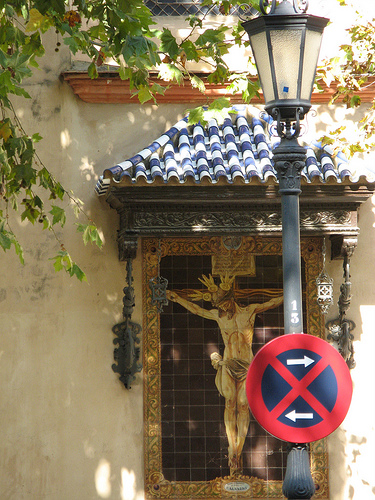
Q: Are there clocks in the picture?
A: No, there are no clocks.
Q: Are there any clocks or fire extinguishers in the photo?
A: No, there are no clocks or fire extinguishers.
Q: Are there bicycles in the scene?
A: No, there are no bicycles.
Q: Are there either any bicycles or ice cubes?
A: No, there are no bicycles or ice cubes.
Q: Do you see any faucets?
A: No, there are no faucets.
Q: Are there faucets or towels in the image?
A: No, there are no faucets or towels.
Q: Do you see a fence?
A: No, there are no fences.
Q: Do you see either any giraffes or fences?
A: No, there are no fences or giraffes.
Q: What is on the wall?
A: The spots are on the wall.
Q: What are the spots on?
A: The spots are on the wall.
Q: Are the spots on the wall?
A: Yes, the spots are on the wall.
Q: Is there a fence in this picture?
A: No, there are no fences.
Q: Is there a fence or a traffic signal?
A: No, there are no fences or traffic lights.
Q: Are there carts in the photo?
A: No, there are no carts.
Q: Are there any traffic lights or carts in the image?
A: No, there are no carts or traffic lights.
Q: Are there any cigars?
A: No, there are no cigars.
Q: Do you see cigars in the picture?
A: No, there are no cigars.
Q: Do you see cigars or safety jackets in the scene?
A: No, there are no cigars or safety jackets.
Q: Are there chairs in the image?
A: No, there are no chairs.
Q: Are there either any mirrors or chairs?
A: No, there are no chairs or mirrors.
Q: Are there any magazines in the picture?
A: No, there are no magazines.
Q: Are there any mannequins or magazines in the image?
A: No, there are no magazines or mannequins.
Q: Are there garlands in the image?
A: No, there are no garlands.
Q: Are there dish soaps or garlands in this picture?
A: No, there are no garlands or dish soaps.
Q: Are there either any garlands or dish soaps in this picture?
A: No, there are no garlands or dish soaps.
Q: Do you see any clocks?
A: No, there are no clocks.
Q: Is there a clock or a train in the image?
A: No, there are no clocks or trains.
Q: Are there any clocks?
A: No, there are no clocks.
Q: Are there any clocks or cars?
A: No, there are no clocks or cars.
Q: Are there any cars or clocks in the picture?
A: No, there are no clocks or cars.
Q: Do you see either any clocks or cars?
A: No, there are no clocks or cars.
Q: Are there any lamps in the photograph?
A: Yes, there is a lamp.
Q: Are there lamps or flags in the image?
A: Yes, there is a lamp.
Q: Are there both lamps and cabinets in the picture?
A: No, there is a lamp but no cabinets.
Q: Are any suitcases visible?
A: No, there are no suitcases.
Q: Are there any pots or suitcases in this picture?
A: No, there are no suitcases or pots.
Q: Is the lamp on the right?
A: Yes, the lamp is on the right of the image.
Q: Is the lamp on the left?
A: No, the lamp is on the right of the image.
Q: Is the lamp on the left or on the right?
A: The lamp is on the right of the image.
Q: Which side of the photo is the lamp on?
A: The lamp is on the right of the image.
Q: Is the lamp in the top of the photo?
A: Yes, the lamp is in the top of the image.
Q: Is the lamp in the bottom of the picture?
A: No, the lamp is in the top of the image.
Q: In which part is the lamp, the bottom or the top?
A: The lamp is in the top of the image.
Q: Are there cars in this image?
A: No, there are no cars.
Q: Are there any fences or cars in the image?
A: No, there are no cars or fences.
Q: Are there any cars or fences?
A: No, there are no cars or fences.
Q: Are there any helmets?
A: No, there are no helmets.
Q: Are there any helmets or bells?
A: No, there are no helmets or bells.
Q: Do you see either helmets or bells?
A: No, there are no helmets or bells.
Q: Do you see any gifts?
A: No, there are no gifts.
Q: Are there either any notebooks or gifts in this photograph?
A: No, there are no gifts or notebooks.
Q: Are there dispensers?
A: No, there are no dispensers.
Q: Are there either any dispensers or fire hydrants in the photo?
A: No, there are no dispensers or fire hydrants.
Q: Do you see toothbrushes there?
A: No, there are no toothbrushes.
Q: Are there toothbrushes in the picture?
A: No, there are no toothbrushes.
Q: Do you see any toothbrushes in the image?
A: No, there are no toothbrushes.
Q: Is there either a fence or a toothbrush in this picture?
A: No, there are no toothbrushes or fences.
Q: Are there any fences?
A: No, there are no fences.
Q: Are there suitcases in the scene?
A: No, there are no suitcases.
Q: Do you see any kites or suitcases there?
A: No, there are no suitcases or kites.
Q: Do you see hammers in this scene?
A: No, there are no hammers.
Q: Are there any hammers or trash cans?
A: No, there are no hammers or trash cans.